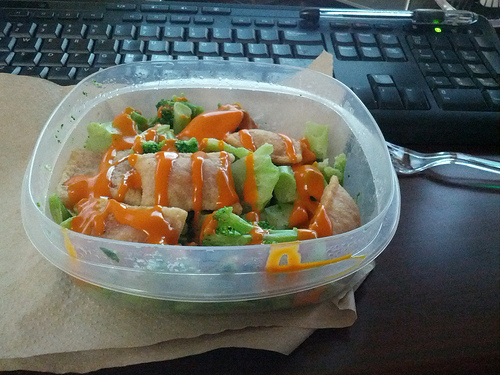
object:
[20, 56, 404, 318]
bowl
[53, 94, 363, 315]
food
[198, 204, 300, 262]
broccoli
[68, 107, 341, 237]
dressing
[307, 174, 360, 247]
dumplings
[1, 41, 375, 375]
napkin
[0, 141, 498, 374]
desk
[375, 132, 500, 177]
fork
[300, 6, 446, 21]
pen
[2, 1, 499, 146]
keyboard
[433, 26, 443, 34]
light